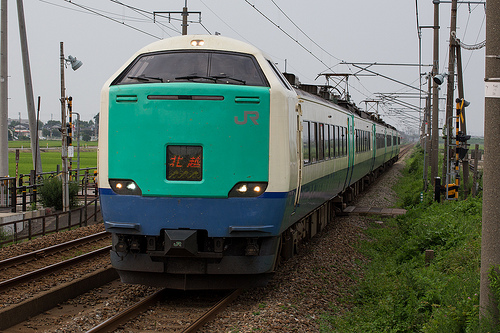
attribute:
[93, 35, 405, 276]
train — green, carred, lit, headlighted, white, black, blue, tracked, powerlined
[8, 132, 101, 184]
grass — green, growing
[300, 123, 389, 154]
windows — black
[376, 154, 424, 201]
track — present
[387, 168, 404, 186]
rocks — brown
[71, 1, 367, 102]
lines — present